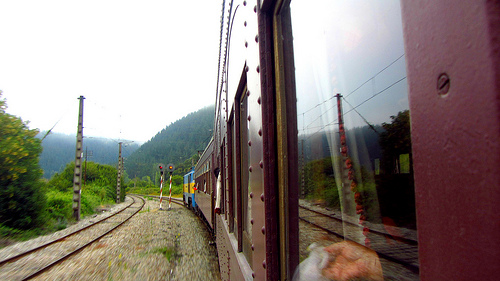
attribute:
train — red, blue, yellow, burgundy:
[178, 0, 499, 280]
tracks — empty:
[13, 189, 151, 278]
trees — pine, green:
[152, 128, 190, 147]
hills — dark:
[124, 103, 214, 195]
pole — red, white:
[166, 173, 180, 213]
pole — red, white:
[156, 167, 170, 211]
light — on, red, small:
[165, 164, 172, 170]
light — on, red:
[156, 163, 164, 173]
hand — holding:
[322, 233, 383, 280]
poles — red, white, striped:
[156, 169, 176, 208]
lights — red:
[156, 162, 174, 175]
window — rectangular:
[229, 90, 260, 277]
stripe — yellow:
[177, 182, 200, 194]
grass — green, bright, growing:
[3, 188, 101, 252]